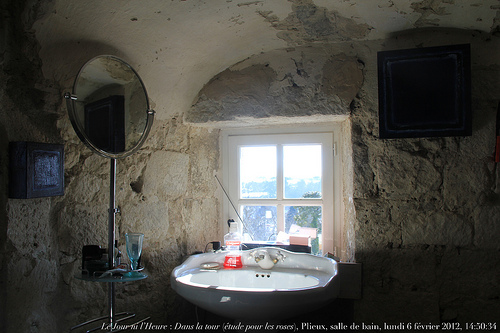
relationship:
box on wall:
[366, 40, 480, 136] [0, 3, 497, 328]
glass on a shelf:
[120, 232, 147, 278] [62, 248, 149, 290]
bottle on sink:
[223, 222, 245, 270] [168, 245, 336, 312]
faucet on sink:
[252, 250, 277, 277] [167, 231, 350, 324]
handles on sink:
[238, 240, 287, 277] [167, 231, 350, 324]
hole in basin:
[250, 270, 260, 278] [164, 240, 334, 325]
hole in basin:
[259, 271, 265, 282] [164, 240, 334, 325]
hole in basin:
[265, 270, 275, 278] [164, 240, 334, 325]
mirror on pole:
[71, 52, 148, 153] [106, 156, 118, 331]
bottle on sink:
[223, 222, 245, 270] [176, 243, 336, 330]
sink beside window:
[171, 243, 346, 318] [223, 134, 330, 252]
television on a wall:
[362, 50, 485, 149] [375, 163, 487, 265]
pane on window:
[232, 142, 278, 200] [218, 124, 337, 256]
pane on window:
[275, 142, 327, 202] [218, 124, 337, 256]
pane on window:
[232, 200, 279, 245] [218, 124, 337, 256]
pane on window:
[281, 205, 326, 256] [218, 124, 337, 256]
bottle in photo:
[215, 218, 250, 273] [0, 2, 498, 331]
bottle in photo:
[223, 222, 245, 270] [0, 2, 498, 331]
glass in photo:
[120, 226, 146, 281] [0, 2, 498, 331]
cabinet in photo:
[1, 143, 66, 203] [0, 2, 498, 331]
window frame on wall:
[205, 111, 344, 247] [114, 26, 418, 286]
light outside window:
[245, 147, 310, 178] [208, 132, 342, 257]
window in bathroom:
[223, 134, 330, 252] [0, 2, 497, 329]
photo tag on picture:
[87, 301, 494, 331] [10, 17, 484, 312]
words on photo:
[100, 318, 497, 330] [0, 2, 498, 331]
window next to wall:
[223, 134, 330, 252] [357, 136, 494, 325]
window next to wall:
[223, 134, 330, 252] [3, 101, 205, 331]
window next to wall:
[223, 134, 330, 252] [192, 44, 377, 114]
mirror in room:
[71, 54, 151, 158] [7, 10, 481, 316]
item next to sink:
[213, 225, 247, 265] [171, 243, 346, 318]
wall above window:
[241, 60, 333, 105] [230, 137, 333, 248]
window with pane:
[223, 134, 330, 252] [234, 147, 274, 200]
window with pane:
[223, 134, 330, 252] [280, 144, 327, 202]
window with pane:
[223, 134, 330, 252] [237, 200, 278, 243]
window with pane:
[223, 134, 330, 252] [283, 199, 326, 246]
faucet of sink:
[249, 249, 287, 269] [171, 243, 346, 318]